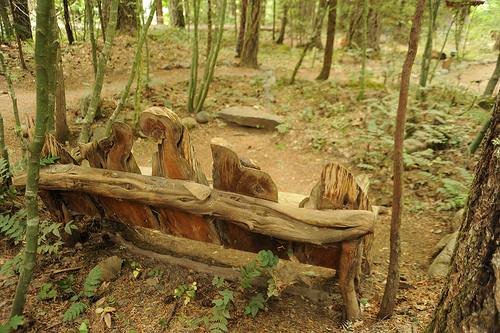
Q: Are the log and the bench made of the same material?
A: Yes, both the log and the bench are made of wood.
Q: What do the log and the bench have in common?
A: The material, both the log and the bench are wooden.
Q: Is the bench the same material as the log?
A: Yes, both the bench and the log are made of wood.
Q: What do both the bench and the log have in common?
A: The material, both the bench and the log are wooden.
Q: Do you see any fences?
A: No, there are no fences.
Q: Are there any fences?
A: No, there are no fences.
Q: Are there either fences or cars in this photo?
A: No, there are no fences or cars.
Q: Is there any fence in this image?
A: No, there are no fences.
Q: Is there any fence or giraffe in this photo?
A: No, there are no fences or giraffes.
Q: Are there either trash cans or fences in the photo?
A: No, there are no fences or trash cans.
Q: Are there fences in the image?
A: No, there are no fences.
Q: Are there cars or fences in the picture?
A: No, there are no fences or cars.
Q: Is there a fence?
A: No, there are no fences.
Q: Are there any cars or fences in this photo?
A: No, there are no fences or cars.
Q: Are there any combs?
A: No, there are no combs.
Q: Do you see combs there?
A: No, there are no combs.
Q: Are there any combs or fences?
A: No, there are no combs or fences.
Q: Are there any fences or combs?
A: No, there are no combs or fences.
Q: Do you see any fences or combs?
A: No, there are no combs or fences.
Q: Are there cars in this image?
A: No, there are no cars.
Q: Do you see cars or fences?
A: No, there are no cars or fences.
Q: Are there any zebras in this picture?
A: No, there are no zebras.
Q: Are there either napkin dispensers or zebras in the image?
A: No, there are no zebras or napkin dispensers.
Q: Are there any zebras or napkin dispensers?
A: No, there are no zebras or napkin dispensers.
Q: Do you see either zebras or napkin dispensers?
A: No, there are no zebras or napkin dispensers.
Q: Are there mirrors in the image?
A: No, there are no mirrors.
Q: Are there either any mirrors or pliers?
A: No, there are no mirrors or pliers.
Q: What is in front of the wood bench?
A: The rock is in front of the bench.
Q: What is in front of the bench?
A: The rock is in front of the bench.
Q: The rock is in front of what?
A: The rock is in front of the bench.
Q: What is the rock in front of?
A: The rock is in front of the bench.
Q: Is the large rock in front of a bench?
A: Yes, the rock is in front of a bench.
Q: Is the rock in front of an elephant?
A: No, the rock is in front of a bench.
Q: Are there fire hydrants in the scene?
A: No, there are no fire hydrants.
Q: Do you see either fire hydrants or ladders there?
A: No, there are no fire hydrants or ladders.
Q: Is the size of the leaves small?
A: Yes, the leaves are small.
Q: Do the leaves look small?
A: Yes, the leaves are small.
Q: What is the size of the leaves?
A: The leaves are small.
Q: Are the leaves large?
A: No, the leaves are small.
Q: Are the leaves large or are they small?
A: The leaves are small.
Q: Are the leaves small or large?
A: The leaves are small.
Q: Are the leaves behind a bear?
A: No, the leaves are behind a bench.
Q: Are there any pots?
A: No, there are no pots.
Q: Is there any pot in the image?
A: No, there are no pots.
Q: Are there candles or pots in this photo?
A: No, there are no pots or candles.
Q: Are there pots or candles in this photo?
A: No, there are no pots or candles.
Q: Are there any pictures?
A: No, there are no pictures.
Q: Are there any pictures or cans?
A: No, there are no pictures or cans.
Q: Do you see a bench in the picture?
A: Yes, there is a bench.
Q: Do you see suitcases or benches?
A: Yes, there is a bench.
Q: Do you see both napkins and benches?
A: No, there is a bench but no napkins.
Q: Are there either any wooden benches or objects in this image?
A: Yes, there is a wood bench.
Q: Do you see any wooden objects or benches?
A: Yes, there is a wood bench.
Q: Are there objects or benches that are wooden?
A: Yes, the bench is wooden.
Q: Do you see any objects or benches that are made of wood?
A: Yes, the bench is made of wood.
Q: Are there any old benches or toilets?
A: Yes, there is an old bench.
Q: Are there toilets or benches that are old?
A: Yes, the bench is old.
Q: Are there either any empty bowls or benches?
A: Yes, there is an empty bench.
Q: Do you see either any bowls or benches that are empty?
A: Yes, the bench is empty.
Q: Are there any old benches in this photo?
A: Yes, there is an old bench.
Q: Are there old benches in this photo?
A: Yes, there is an old bench.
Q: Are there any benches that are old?
A: Yes, there is a bench that is old.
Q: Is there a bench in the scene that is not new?
A: Yes, there is a old bench.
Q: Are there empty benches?
A: Yes, there is an empty bench.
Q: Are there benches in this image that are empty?
A: Yes, there is a bench that is empty.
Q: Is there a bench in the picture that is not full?
A: Yes, there is a empty bench.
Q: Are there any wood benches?
A: Yes, there is a wood bench.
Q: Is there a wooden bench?
A: Yes, there is a wood bench.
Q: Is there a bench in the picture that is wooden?
A: Yes, there is a bench that is wooden.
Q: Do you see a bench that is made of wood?
A: Yes, there is a bench that is made of wood.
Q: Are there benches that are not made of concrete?
A: Yes, there is a bench that is made of wood.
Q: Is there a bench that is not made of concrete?
A: Yes, there is a bench that is made of wood.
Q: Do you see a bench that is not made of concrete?
A: Yes, there is a bench that is made of wood.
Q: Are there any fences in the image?
A: No, there are no fences.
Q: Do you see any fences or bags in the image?
A: No, there are no fences or bags.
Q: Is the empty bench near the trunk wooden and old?
A: Yes, the bench is wooden and old.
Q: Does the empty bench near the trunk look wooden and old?
A: Yes, the bench is wooden and old.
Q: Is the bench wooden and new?
A: No, the bench is wooden but old.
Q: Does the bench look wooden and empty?
A: Yes, the bench is wooden and empty.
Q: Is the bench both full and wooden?
A: No, the bench is wooden but empty.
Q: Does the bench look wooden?
A: Yes, the bench is wooden.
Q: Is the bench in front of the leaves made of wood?
A: Yes, the bench is made of wood.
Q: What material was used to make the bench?
A: The bench is made of wood.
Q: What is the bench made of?
A: The bench is made of wood.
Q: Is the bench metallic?
A: No, the bench is wooden.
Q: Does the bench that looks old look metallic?
A: No, the bench is wooden.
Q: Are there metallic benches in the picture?
A: No, there is a bench but it is wooden.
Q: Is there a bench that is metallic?
A: No, there is a bench but it is wooden.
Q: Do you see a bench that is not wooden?
A: No, there is a bench but it is wooden.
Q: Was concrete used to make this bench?
A: No, the bench is made of wood.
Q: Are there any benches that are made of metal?
A: No, there is a bench but it is made of wood.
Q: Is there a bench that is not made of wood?
A: No, there is a bench but it is made of wood.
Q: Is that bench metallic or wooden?
A: The bench is wooden.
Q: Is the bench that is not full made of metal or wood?
A: The bench is made of wood.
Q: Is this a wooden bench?
A: Yes, this is a wooden bench.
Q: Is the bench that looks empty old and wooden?
A: Yes, the bench is old and wooden.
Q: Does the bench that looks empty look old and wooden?
A: Yes, the bench is old and wooden.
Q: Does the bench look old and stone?
A: No, the bench is old but wooden.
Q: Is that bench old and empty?
A: Yes, the bench is old and empty.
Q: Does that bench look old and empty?
A: Yes, the bench is old and empty.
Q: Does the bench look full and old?
A: No, the bench is old but empty.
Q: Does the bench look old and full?
A: No, the bench is old but empty.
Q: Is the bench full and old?
A: No, the bench is old but empty.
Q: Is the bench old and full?
A: No, the bench is old but empty.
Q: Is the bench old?
A: Yes, the bench is old.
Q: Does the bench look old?
A: Yes, the bench is old.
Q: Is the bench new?
A: No, the bench is old.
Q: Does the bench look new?
A: No, the bench is old.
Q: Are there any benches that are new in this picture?
A: No, there is a bench but it is old.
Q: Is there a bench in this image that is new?
A: No, there is a bench but it is old.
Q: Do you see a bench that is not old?
A: No, there is a bench but it is old.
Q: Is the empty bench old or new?
A: The bench is old.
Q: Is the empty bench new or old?
A: The bench is old.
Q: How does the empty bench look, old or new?
A: The bench is old.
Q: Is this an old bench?
A: Yes, this is an old bench.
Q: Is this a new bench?
A: No, this is an old bench.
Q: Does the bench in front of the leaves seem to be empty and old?
A: Yes, the bench is empty and old.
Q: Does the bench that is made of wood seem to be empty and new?
A: No, the bench is empty but old.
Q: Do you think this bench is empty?
A: Yes, the bench is empty.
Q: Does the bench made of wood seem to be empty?
A: Yes, the bench is empty.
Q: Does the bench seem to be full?
A: No, the bench is empty.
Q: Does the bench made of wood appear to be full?
A: No, the bench is empty.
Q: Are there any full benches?
A: No, there is a bench but it is empty.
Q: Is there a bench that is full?
A: No, there is a bench but it is empty.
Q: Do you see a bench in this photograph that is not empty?
A: No, there is a bench but it is empty.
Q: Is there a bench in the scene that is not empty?
A: No, there is a bench but it is empty.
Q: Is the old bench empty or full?
A: The bench is empty.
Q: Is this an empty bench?
A: Yes, this is an empty bench.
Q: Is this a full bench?
A: No, this is an empty bench.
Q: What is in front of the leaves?
A: The bench is in front of the leaves.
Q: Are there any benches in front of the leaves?
A: Yes, there is a bench in front of the leaves.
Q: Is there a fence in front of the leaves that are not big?
A: No, there is a bench in front of the leaves.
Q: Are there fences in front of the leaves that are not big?
A: No, there is a bench in front of the leaves.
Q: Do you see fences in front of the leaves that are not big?
A: No, there is a bench in front of the leaves.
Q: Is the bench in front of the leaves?
A: Yes, the bench is in front of the leaves.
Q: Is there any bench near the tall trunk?
A: Yes, there is a bench near the trunk.